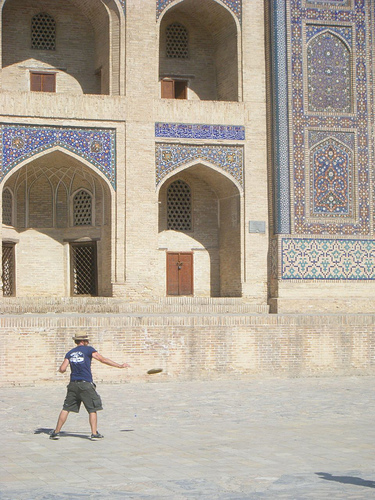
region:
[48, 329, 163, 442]
a man throwing a frisbee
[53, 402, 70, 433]
the leg of a man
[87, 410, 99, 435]
the leg of a man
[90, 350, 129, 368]
the arm of a man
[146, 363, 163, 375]
a gold frisbee in the air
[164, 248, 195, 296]
a brown door to a beige building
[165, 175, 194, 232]
a window with holes on a building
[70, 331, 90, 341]
a man with a yellow hat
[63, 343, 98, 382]
a man with a blue shirt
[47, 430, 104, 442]
a man with black shoes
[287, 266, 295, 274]
blue design on building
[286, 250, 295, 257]
blue design on building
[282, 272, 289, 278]
blue design on building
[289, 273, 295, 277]
blue design on building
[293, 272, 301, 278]
blue design on building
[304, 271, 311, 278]
blue design on building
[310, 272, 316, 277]
blue design on building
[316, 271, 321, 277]
blue design on building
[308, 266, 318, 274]
blue design on building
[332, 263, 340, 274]
blue design on building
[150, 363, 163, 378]
frisbee in the air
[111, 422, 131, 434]
shadow of frisbee on the ground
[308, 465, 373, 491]
shadow of a person on the ground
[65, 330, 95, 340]
man is wearing a hat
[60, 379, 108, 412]
man is wearing cargo shorts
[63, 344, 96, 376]
man is wearing a blue shirt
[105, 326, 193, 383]
brick wall behind the man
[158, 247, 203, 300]
wooden doors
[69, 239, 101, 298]
lattice on the window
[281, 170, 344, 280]
colorful tiled wall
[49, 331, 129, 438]
A person in a brown hat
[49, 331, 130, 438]
A person in a blue t-shirt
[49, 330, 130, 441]
A person in a dark green pants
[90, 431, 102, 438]
A black shoe with white bottom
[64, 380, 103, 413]
A pair of dark colored short pants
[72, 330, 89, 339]
A light brown hat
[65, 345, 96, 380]
A blue t-shirt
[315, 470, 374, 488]
A shadow of a person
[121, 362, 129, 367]
Right hand of a person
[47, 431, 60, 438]
Left foot of a person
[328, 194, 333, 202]
white tile on building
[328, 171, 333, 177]
white tile on building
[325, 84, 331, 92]
white tile on building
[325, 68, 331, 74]
white tile on building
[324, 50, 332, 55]
white tile on building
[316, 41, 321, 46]
white tile on building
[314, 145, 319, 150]
white tile on building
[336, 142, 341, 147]
white tile on building